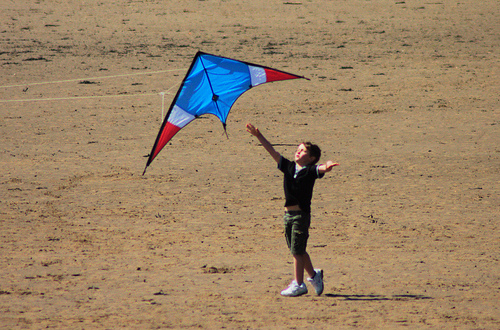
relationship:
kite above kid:
[119, 37, 309, 173] [245, 121, 337, 296]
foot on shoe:
[279, 276, 308, 296] [280, 281, 308, 296]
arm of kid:
[315, 159, 336, 176] [245, 121, 337, 296]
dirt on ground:
[4, 3, 499, 328] [2, 2, 497, 325]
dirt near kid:
[84, 216, 217, 307] [229, 122, 366, 277]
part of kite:
[183, 43, 223, 78] [112, 33, 337, 165]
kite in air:
[119, 37, 309, 173] [94, 16, 197, 42]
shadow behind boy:
[322, 286, 438, 306] [242, 124, 342, 299]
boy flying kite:
[242, 124, 342, 299] [119, 37, 309, 173]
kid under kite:
[235, 122, 403, 227] [244, 124, 336, 297]